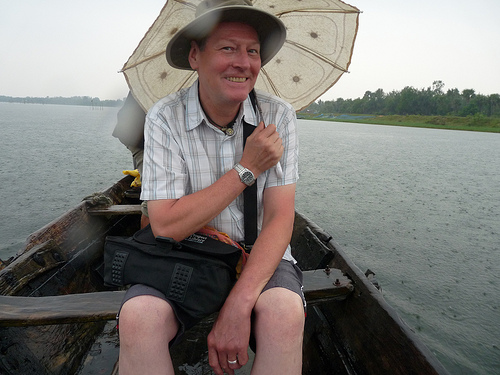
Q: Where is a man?
A: In a boat.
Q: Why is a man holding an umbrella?
A: It is raining.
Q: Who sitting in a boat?
A: A man.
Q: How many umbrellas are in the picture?
A: One.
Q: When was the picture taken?
A: Daytime.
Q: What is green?
A: Grass.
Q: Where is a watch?
A: On man's wrist.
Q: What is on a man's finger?
A: Wedding ring.